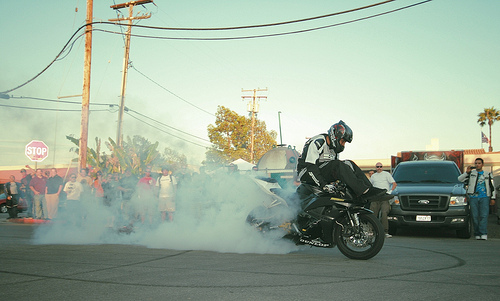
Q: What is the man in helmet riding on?
A: Motorcycle.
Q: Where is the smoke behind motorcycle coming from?
A: Exhaust pipe.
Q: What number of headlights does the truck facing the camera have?
A: 2.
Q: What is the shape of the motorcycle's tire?
A: Round.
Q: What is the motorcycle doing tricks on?
A: Asphalt.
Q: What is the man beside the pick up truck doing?
A: Watching motorcycle rider.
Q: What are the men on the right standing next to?
A: Pickup truck.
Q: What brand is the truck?
A: Ford.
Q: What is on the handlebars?
A: Legs.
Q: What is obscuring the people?
A: Smoke.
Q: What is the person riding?
A: Motorcycle.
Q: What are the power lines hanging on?
A: Power pole.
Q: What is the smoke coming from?
A: Motorcycle.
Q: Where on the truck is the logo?
A: The grill.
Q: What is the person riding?
A: Motorcycle.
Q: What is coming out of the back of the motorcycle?
A: Smoke.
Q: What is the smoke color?
A: White.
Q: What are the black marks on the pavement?
A: Skid marks.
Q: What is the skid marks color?
A: Black.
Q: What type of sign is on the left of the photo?
A: Stop.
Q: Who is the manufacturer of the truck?
A: Ford.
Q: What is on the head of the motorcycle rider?
A: Helmet.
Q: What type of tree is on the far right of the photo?
A: Palm.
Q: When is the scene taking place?
A: Daytime.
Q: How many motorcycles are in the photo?
A: One.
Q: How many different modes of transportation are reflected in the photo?
A: Two.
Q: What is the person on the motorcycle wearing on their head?
A: Helmet.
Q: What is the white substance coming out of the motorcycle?
A: Smoke.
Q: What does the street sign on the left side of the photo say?
A: Stop.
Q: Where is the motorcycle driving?
A: Street.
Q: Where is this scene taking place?
A: On a road.